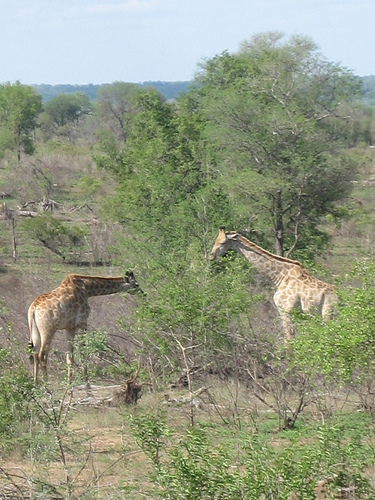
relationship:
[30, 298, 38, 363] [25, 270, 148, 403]
tail belongs to giraffe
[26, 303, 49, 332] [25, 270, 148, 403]
rear belongs to giraffe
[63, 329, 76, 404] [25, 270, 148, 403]
leg belongs to giraffe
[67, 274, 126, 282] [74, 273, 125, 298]
hair on neck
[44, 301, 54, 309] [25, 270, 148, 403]
spot on coat of giraffe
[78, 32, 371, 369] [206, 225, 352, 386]
tree near giraffe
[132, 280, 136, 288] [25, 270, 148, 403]
eye belongs to giraffe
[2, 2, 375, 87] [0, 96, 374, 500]
sky above ground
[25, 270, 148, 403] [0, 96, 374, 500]
giraffe on ground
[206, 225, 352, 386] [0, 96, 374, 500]
giraffe on ground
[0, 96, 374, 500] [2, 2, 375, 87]
ground below sky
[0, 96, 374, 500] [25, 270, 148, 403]
ground below giraffe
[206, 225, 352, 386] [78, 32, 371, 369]
giraffe eating tree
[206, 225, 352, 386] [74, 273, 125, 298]
giraffe has neck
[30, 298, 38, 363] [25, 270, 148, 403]
tail apart of giraffe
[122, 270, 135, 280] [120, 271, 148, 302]
horn on head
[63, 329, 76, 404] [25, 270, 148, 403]
leg apart of giraffe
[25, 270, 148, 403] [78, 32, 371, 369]
giraffe eating tree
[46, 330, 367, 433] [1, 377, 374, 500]
branches are on grass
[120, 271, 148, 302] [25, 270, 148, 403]
head belongs to giraffe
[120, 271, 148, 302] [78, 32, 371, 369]
head in tree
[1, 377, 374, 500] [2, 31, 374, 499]
grass on savannah